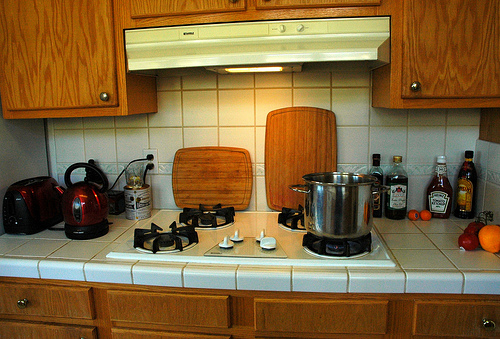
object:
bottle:
[426, 155, 454, 219]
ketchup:
[425, 177, 452, 219]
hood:
[125, 16, 390, 75]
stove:
[132, 220, 197, 254]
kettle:
[54, 162, 109, 239]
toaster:
[3, 176, 66, 236]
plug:
[146, 154, 153, 161]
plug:
[146, 163, 154, 170]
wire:
[108, 158, 147, 190]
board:
[172, 146, 253, 211]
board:
[263, 106, 337, 211]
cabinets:
[0, 0, 500, 120]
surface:
[105, 209, 394, 266]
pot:
[289, 172, 381, 239]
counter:
[0, 208, 500, 339]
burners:
[106, 209, 395, 267]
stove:
[278, 204, 305, 230]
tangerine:
[408, 209, 420, 220]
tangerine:
[420, 210, 432, 221]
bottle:
[455, 150, 477, 219]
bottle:
[383, 155, 408, 220]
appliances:
[123, 162, 151, 220]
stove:
[180, 203, 236, 228]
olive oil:
[385, 174, 408, 219]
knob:
[218, 236, 234, 248]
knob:
[255, 229, 267, 242]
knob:
[260, 237, 277, 250]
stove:
[302, 231, 372, 257]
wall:
[57, 98, 470, 225]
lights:
[225, 67, 283, 74]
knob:
[230, 229, 244, 242]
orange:
[479, 224, 499, 253]